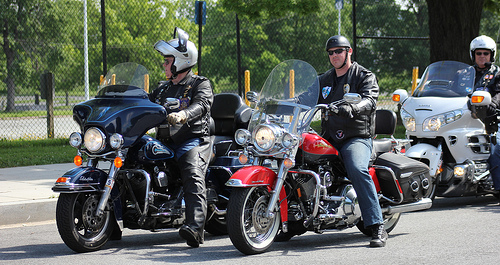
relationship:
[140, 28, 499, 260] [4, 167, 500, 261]
three motorcyclists are on road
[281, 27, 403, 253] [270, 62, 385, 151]
motorcyclist wearing black outfit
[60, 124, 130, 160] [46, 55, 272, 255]
three lights in front of motorcycle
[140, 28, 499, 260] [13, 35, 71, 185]
three motorcyclists are traveling to left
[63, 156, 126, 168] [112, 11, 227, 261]
orange lights are in front of motorcyclist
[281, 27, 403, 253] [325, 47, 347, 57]
motorcyclist has sunglasses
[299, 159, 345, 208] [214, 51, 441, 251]
engine of motorcycle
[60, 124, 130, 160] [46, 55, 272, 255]
three lights of motorcycle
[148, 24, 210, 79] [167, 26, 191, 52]
helmet with visor up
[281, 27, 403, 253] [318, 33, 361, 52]
motorcyclist wearing helmet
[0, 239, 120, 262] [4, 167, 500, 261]
shadow on road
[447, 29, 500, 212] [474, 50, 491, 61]
motorcyclist wears sunglasses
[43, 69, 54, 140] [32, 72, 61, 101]
wooden post has sign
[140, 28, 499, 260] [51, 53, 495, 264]
three motorcyclists are riding motorcycles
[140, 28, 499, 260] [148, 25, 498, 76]
three motorcyclists are wearing helmets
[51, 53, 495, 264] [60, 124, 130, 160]
motorcycles have three lights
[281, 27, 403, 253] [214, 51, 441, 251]
motorcyclist has motorcycle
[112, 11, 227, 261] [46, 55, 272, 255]
motorcyclist rides motorcycle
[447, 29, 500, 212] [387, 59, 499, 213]
motorcyclist rides motorcycle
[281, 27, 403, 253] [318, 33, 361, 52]
motorcyclist wears helmet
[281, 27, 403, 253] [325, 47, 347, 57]
motorcyclist wears sunglasses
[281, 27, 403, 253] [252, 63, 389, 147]
motorcyclist wears leather chaps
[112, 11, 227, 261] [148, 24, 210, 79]
motorcyclist wears helmet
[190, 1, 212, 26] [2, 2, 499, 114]
sign at park